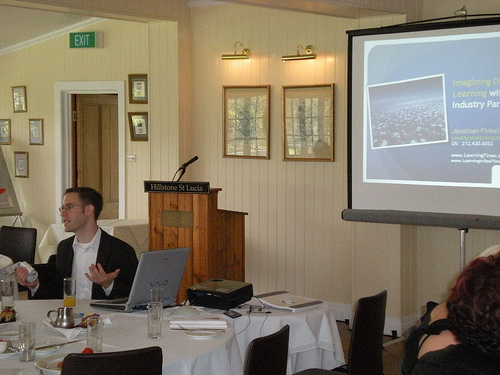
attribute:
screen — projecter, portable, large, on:
[345, 25, 499, 231]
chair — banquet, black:
[62, 343, 165, 371]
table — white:
[7, 272, 343, 375]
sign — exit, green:
[72, 25, 99, 52]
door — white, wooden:
[55, 73, 124, 226]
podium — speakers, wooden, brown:
[145, 172, 247, 310]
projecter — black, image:
[187, 275, 259, 314]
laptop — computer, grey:
[99, 243, 195, 308]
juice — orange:
[64, 276, 77, 310]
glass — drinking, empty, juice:
[145, 301, 173, 346]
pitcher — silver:
[47, 309, 88, 328]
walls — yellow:
[7, 14, 488, 317]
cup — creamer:
[48, 303, 93, 336]